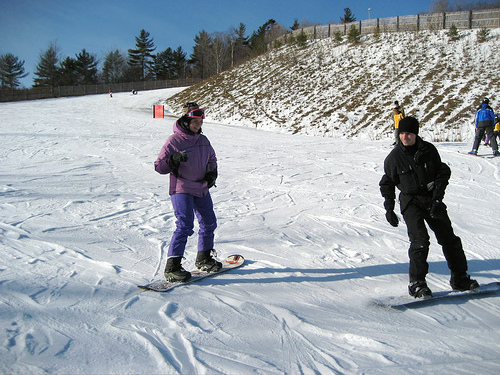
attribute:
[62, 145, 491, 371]
snow — white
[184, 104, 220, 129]
goggles — red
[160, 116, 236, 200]
jacket — purple, purplet, blue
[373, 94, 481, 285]
man — looking, dressed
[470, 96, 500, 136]
jacket — blue, yellow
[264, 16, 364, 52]
trees — small, green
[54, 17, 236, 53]
sky — dark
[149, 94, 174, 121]
sign — orange, red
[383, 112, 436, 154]
cap — black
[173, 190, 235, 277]
pants — purple, blue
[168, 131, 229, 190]
coat — lavender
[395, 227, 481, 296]
boots — black